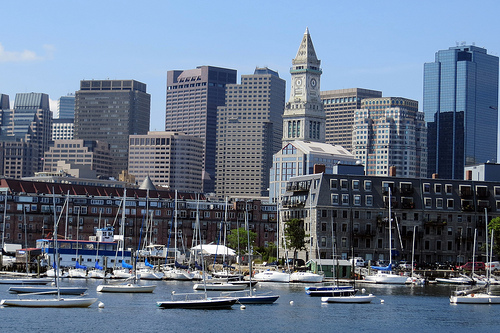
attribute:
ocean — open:
[2, 269, 499, 331]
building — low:
[276, 177, 495, 294]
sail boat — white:
[318, 288, 377, 303]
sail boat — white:
[93, 284, 156, 291]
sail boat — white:
[1, 185, 98, 306]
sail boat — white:
[362, 184, 412, 284]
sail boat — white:
[450, 229, 499, 303]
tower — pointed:
[282, 25, 324, 142]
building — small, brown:
[269, 141, 366, 203]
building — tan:
[213, 66, 286, 201]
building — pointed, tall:
[278, 25, 327, 147]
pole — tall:
[188, 194, 213, 297]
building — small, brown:
[3, 165, 275, 265]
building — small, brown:
[280, 173, 497, 269]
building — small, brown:
[352, 94, 427, 180]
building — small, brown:
[417, 37, 489, 167]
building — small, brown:
[321, 89, 388, 166]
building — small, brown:
[280, 21, 333, 141]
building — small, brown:
[220, 58, 277, 196]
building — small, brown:
[130, 130, 207, 190]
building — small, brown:
[162, 60, 232, 182]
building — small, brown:
[72, 74, 146, 189]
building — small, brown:
[42, 140, 105, 188]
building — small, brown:
[1, 89, 53, 181]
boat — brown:
[158, 294, 238, 309]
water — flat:
[0, 269, 495, 331]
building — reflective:
[423, 45, 498, 196]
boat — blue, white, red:
[36, 224, 133, 275]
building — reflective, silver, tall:
[419, 40, 498, 173]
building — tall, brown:
[169, 70, 209, 180]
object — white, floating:
[157, 200, 276, 322]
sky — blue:
[9, 9, 482, 111]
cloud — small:
[9, 37, 69, 67]